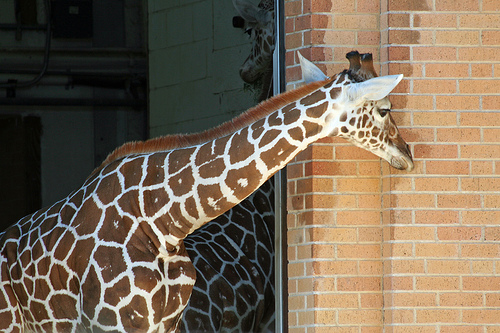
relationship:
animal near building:
[0, 49, 411, 333] [160, 0, 496, 330]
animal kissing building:
[0, 49, 411, 333] [1, 0, 499, 332]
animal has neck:
[18, 52, 390, 325] [151, 96, 311, 238]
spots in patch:
[234, 176, 246, 189] [228, 160, 264, 202]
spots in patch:
[202, 190, 219, 210] [199, 179, 238, 219]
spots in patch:
[173, 176, 186, 187] [163, 167, 194, 196]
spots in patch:
[105, 215, 125, 235] [96, 202, 136, 246]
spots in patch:
[126, 308, 149, 322] [117, 296, 149, 330]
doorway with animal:
[1, 0, 283, 331] [0, 49, 411, 333]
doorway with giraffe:
[1, 0, 283, 331] [169, 172, 289, 329]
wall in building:
[36, 39, 235, 107] [12, 7, 480, 312]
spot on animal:
[287, 122, 304, 144] [0, 49, 411, 333]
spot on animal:
[282, 102, 299, 126] [0, 49, 411, 333]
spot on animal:
[299, 90, 324, 107] [0, 49, 411, 333]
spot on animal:
[257, 137, 298, 167] [0, 49, 411, 333]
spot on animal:
[193, 181, 235, 216] [0, 49, 411, 333]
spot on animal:
[195, 134, 228, 161] [0, 49, 411, 333]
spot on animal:
[163, 163, 198, 196] [0, 49, 411, 333]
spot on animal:
[194, 147, 222, 180] [0, 49, 411, 333]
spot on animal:
[141, 145, 169, 187] [0, 49, 411, 333]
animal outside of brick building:
[0, 49, 411, 333] [280, 1, 497, 331]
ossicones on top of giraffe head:
[342, 42, 379, 82] [304, 59, 442, 203]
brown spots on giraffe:
[71, 232, 136, 293] [57, 22, 419, 250]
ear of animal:
[347, 74, 403, 103] [0, 49, 411, 333]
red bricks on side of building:
[411, 44, 458, 63] [283, 0, 498, 332]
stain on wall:
[284, 6, 344, 236] [281, 3, 498, 328]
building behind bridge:
[349, 208, 403, 263] [107, 95, 151, 111]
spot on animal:
[224, 160, 262, 199] [0, 49, 411, 333]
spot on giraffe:
[163, 147, 194, 168] [18, 42, 429, 311]